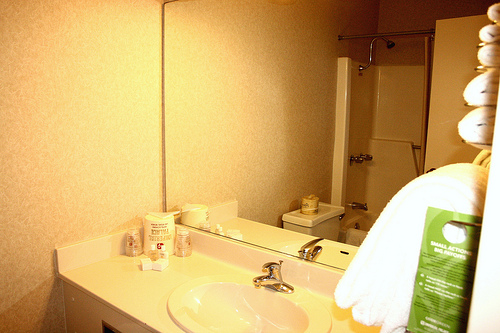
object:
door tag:
[408, 202, 487, 331]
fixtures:
[250, 260, 296, 295]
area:
[338, 217, 368, 245]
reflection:
[164, 19, 495, 246]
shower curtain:
[422, 26, 434, 178]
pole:
[335, 28, 432, 41]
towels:
[454, 106, 500, 150]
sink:
[165, 276, 332, 331]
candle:
[144, 214, 178, 258]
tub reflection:
[343, 211, 376, 245]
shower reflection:
[349, 33, 394, 213]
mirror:
[162, 0, 499, 279]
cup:
[125, 227, 144, 256]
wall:
[162, 0, 477, 331]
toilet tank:
[279, 202, 343, 241]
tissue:
[300, 195, 320, 215]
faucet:
[253, 258, 297, 296]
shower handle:
[349, 153, 373, 166]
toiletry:
[171, 228, 193, 258]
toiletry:
[146, 244, 160, 261]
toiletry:
[144, 213, 173, 255]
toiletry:
[123, 223, 142, 254]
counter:
[53, 219, 365, 332]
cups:
[176, 228, 192, 258]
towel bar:
[412, 140, 423, 151]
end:
[410, 143, 421, 152]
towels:
[325, 161, 498, 333]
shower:
[359, 37, 397, 72]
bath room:
[0, 4, 495, 330]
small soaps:
[152, 259, 169, 272]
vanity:
[52, 214, 387, 331]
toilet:
[281, 201, 347, 241]